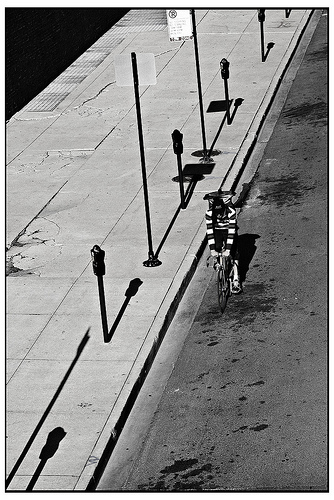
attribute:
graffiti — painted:
[78, 449, 105, 468]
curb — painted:
[103, 314, 159, 436]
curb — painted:
[246, 64, 281, 144]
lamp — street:
[118, 52, 158, 104]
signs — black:
[109, 10, 201, 90]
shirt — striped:
[205, 204, 240, 256]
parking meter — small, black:
[91, 244, 110, 341]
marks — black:
[259, 82, 317, 133]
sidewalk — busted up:
[17, 216, 82, 373]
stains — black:
[162, 434, 231, 498]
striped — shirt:
[205, 217, 235, 247]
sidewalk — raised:
[6, 8, 314, 489]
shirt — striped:
[202, 207, 234, 256]